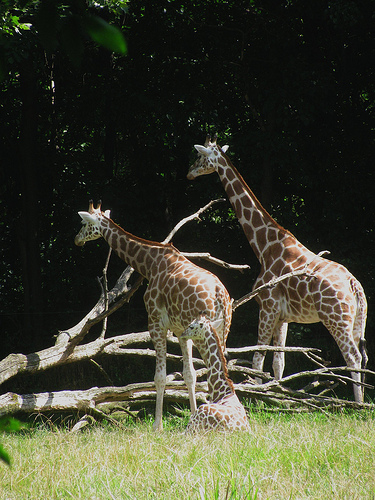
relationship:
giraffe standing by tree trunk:
[188, 140, 368, 403] [0, 387, 100, 416]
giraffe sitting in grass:
[76, 200, 234, 426] [73, 433, 289, 490]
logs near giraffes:
[1, 231, 347, 420] [73, 133, 368, 433]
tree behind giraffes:
[260, 0, 375, 210] [73, 133, 368, 433]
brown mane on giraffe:
[228, 160, 330, 269] [184, 138, 370, 402]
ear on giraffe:
[219, 144, 229, 153] [184, 138, 370, 402]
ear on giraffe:
[193, 143, 209, 155] [184, 138, 370, 402]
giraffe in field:
[76, 200, 234, 426] [1, 395, 373, 498]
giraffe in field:
[188, 140, 368, 403] [1, 395, 373, 498]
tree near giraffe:
[8, 193, 374, 423] [76, 200, 234, 426]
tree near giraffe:
[8, 193, 374, 423] [188, 140, 368, 403]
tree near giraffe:
[8, 193, 374, 423] [181, 311, 250, 432]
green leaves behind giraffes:
[23, 14, 356, 272] [185, 120, 374, 485]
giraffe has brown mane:
[76, 200, 234, 426] [219, 146, 295, 238]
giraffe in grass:
[157, 314, 251, 433] [1, 396, 374, 498]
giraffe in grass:
[76, 200, 234, 426] [1, 396, 374, 498]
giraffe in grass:
[184, 138, 370, 402] [1, 396, 374, 498]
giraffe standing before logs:
[34, 177, 291, 463] [2, 195, 372, 417]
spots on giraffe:
[154, 263, 189, 305] [76, 200, 234, 426]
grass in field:
[150, 429, 217, 466] [8, 415, 356, 489]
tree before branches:
[260, 0, 375, 210] [0, 197, 375, 431]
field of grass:
[1, 395, 373, 498] [1, 435, 373, 498]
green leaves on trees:
[0, 0, 138, 205] [15, 122, 242, 287]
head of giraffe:
[184, 136, 232, 182] [184, 138, 370, 402]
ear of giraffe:
[66, 200, 99, 227] [53, 200, 248, 405]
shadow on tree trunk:
[22, 351, 40, 371] [0, 337, 99, 414]